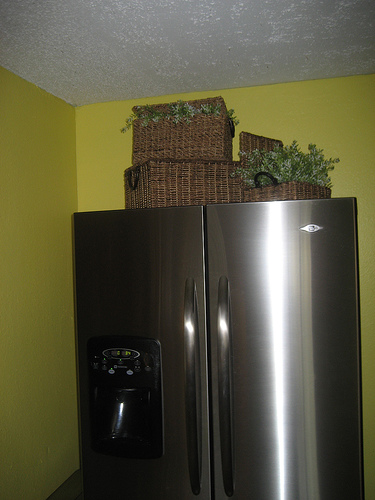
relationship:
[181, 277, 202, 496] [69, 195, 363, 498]
handle on front of door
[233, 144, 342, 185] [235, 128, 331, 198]
green plant inside of basket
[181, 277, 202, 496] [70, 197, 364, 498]
handle on front of fridge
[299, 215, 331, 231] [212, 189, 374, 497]
logo stuck to door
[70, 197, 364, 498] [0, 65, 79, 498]
fridge sitting beside wall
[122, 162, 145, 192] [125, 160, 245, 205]
handle on side of basket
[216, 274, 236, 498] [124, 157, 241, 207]
handle on basket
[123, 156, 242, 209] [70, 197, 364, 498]
basket on fridge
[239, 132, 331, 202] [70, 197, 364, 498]
basket on fridge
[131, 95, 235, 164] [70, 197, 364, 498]
basket on fridge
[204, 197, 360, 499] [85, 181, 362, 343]
door on fridge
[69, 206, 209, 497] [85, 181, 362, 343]
door on fridge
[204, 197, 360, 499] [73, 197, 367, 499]
door on fridge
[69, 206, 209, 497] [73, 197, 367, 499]
door on fridge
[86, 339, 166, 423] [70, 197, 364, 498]
water filter on fridge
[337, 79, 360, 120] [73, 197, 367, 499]
wall behind fridge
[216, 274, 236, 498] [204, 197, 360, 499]
handle on door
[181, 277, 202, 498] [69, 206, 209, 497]
handle on door